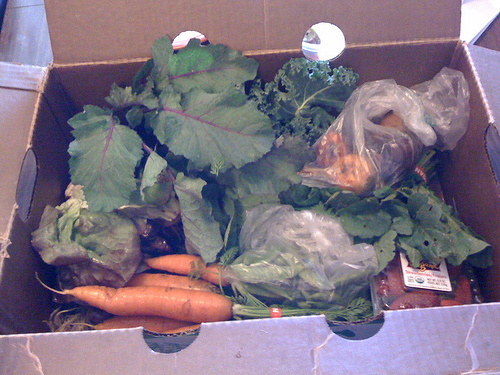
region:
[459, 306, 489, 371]
crack in the cardboard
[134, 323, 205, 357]
semi-circle cutout in the cardboard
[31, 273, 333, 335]
orange carrot with a green top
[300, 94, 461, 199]
food in a clear plastic bag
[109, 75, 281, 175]
large green leaf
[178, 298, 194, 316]
dark spot on the carrot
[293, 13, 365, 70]
circle cutout in the cardboard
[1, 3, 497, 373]
food in a cardboard box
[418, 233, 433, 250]
small hole in the leaf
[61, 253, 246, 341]
group of carrots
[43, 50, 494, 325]
a box of produce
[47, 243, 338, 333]
carrots in a box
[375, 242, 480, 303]
strawberries in a box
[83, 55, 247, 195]
lettuce in a box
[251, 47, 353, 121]
kale in a box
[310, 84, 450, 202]
radish in a box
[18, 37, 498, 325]
the box is made of cardboard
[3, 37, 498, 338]
the box on a table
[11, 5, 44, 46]
the table is made of wood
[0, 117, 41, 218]
the handle of the box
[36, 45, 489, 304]
Box full of vegetables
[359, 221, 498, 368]
Container of red strawberries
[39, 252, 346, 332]
Orange carrots with green stems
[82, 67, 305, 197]
Green bunch of lettuce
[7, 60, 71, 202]
Brown cardboard box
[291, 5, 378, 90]
Hole in side of box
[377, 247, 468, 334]
Label on strawberry container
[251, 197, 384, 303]
Plastic bag holding vegetables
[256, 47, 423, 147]
Bushy lettuce leaf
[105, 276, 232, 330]
Dirt on carrot stem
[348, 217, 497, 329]
box of strawberries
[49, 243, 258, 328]
a whole orange carrot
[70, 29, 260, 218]
a healthy green leaf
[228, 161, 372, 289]
plastic bag in the box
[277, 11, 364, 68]
a hole in the box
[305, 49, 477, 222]
a bag of vegetables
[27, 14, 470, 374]
a cardboard box full of vegetables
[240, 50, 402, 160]
green kale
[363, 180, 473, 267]
lettuce in a box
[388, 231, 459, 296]
white tag on strawberries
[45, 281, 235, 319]
FRESH ORANGE CARROT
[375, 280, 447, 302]
STRAWBERRIES IN A PLASTIC CONTAINER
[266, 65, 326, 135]
GREEN RUFFLED CABBAGE LEAF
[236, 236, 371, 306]
GREEN SNOW PEAS IN PLASTIC BAG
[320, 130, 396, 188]
RED,GOLD, PURPLE PEPPERS IN BAG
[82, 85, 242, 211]
FRESH BEET LEAVES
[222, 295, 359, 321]
FRESH GREEN CARROT TOP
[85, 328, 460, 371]
WHITE WAX COATED CARDBOARD BOX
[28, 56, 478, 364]
BOX CONTAINING FRESH PRODUCE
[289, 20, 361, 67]
HOLE IN CARDBOARD BOX